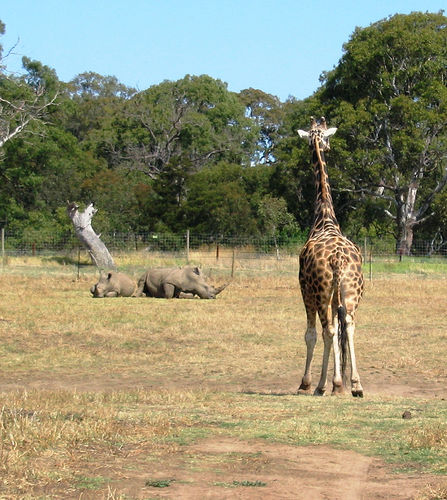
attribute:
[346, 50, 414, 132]
tree — big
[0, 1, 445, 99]
sky — clear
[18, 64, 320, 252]
trees — green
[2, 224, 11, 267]
post — small, wooden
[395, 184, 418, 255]
trunk — wide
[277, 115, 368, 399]
giraffe — brown, white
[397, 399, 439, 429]
stone — tan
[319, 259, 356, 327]
tail — long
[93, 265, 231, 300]
animal — horned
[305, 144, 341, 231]
neck — long